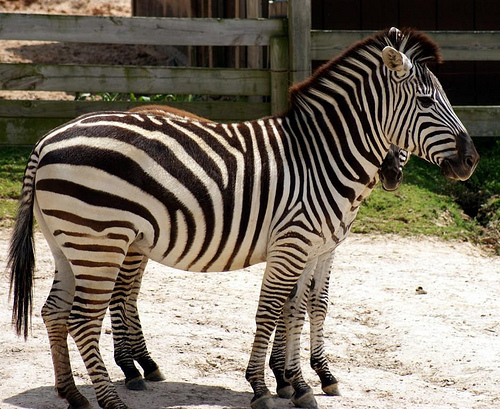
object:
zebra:
[5, 25, 482, 408]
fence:
[0, 1, 499, 137]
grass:
[1, 147, 496, 233]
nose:
[442, 144, 481, 173]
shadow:
[3, 263, 314, 381]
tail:
[2, 156, 37, 341]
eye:
[416, 89, 431, 112]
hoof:
[248, 324, 279, 388]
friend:
[95, 104, 410, 399]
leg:
[243, 214, 341, 397]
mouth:
[444, 156, 466, 182]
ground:
[1, 231, 498, 409]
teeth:
[381, 179, 401, 194]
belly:
[140, 240, 266, 273]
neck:
[288, 57, 384, 214]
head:
[378, 25, 480, 180]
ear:
[378, 45, 412, 73]